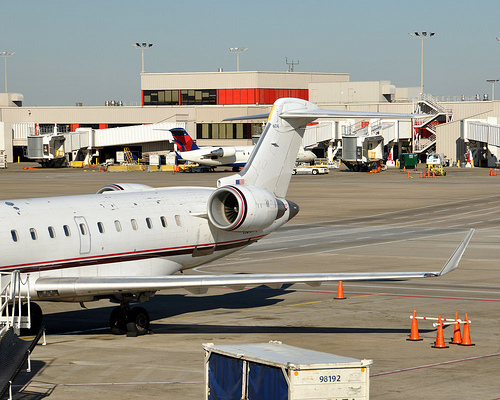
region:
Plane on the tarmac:
[0, 96, 470, 336]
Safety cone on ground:
[331, 277, 351, 305]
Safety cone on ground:
[400, 304, 427, 347]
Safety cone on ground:
[429, 314, 449, 355]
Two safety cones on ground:
[449, 309, 474, 349]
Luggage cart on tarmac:
[195, 325, 374, 399]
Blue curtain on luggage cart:
[245, 359, 288, 399]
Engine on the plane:
[205, 181, 297, 238]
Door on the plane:
[68, 214, 98, 260]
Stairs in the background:
[403, 90, 446, 168]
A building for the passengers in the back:
[6, 69, 498, 172]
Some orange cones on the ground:
[406, 308, 472, 346]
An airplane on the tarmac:
[1, 98, 475, 333]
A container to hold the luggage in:
[196, 338, 371, 398]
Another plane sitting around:
[158, 120, 315, 170]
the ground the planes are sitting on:
[4, 170, 499, 399]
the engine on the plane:
[206, 183, 284, 235]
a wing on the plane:
[40, 226, 479, 293]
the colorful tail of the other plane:
[163, 129, 195, 150]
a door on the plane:
[71, 215, 96, 255]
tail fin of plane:
[211, 98, 405, 130]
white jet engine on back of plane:
[206, 182, 285, 233]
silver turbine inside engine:
[218, 188, 235, 217]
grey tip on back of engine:
[274, 198, 289, 215]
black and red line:
[92, 242, 188, 262]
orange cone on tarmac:
[390, 309, 478, 351]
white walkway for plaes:
[97, 125, 190, 152]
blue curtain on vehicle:
[204, 355, 246, 395]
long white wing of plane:
[69, 268, 385, 290]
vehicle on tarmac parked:
[292, 163, 331, 179]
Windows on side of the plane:
[8, 211, 186, 247]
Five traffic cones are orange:
[331, 274, 478, 352]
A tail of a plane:
[221, 93, 438, 196]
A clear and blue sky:
[1, 1, 499, 104]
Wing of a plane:
[34, 225, 477, 305]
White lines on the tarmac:
[191, 193, 497, 272]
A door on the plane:
[70, 210, 96, 258]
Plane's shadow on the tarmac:
[39, 276, 451, 340]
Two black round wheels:
[106, 299, 155, 341]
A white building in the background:
[2, 67, 426, 158]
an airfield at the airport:
[14, 19, 477, 359]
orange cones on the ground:
[407, 297, 497, 354]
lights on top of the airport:
[97, 29, 434, 64]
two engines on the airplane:
[86, 171, 280, 233]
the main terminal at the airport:
[114, 57, 412, 157]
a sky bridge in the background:
[30, 119, 190, 161]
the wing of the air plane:
[32, 247, 497, 298]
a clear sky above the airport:
[38, 15, 401, 59]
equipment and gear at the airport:
[327, 108, 465, 181]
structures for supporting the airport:
[11, 114, 445, 182]